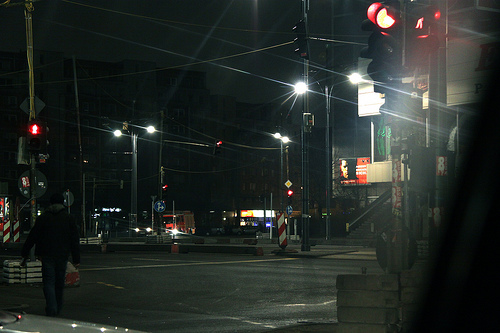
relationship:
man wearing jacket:
[20, 195, 81, 316] [23, 216, 79, 261]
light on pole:
[292, 80, 311, 102] [294, 54, 314, 253]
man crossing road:
[20, 192, 81, 316] [0, 235, 385, 333]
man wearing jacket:
[20, 192, 81, 316] [36, 207, 81, 255]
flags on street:
[272, 207, 291, 256] [28, 239, 369, 310]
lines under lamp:
[81, 109, 282, 161] [145, 122, 157, 134]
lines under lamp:
[81, 109, 282, 161] [271, 130, 281, 140]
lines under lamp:
[81, 109, 282, 161] [111, 129, 123, 136]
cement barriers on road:
[1, 241, 91, 307] [0, 235, 385, 333]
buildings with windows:
[1, 47, 233, 198] [18, 70, 235, 212]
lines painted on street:
[82, 252, 299, 271] [0, 244, 388, 330]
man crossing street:
[20, 192, 81, 316] [165, 254, 290, 332]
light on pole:
[294, 81, 308, 94] [292, 104, 317, 251]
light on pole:
[294, 81, 308, 94] [298, 92, 312, 255]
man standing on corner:
[20, 192, 81, 316] [2, 237, 125, 331]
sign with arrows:
[152, 197, 167, 212] [155, 199, 164, 213]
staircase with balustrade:
[334, 180, 384, 245] [348, 188, 397, 240]